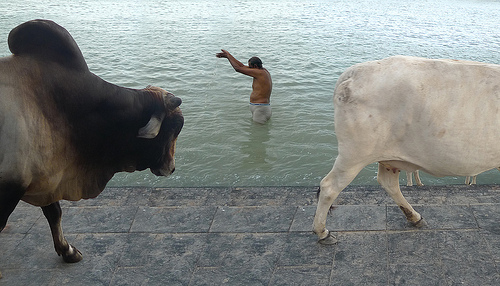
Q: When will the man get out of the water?
A: When he has finished bathing in the water.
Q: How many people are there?
A: One.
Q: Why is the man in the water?
A: He is bathing in the water.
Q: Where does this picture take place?
A: Outside near a lake.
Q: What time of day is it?
A: Daytime.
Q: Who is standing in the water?
A: A man.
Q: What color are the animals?
A: White and black.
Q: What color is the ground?
A: Gray.